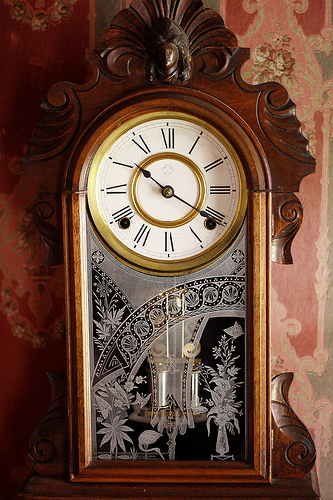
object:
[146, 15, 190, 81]
carved head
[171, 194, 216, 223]
hand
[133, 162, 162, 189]
hand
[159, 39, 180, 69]
carved face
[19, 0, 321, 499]
grandfather clock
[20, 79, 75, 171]
carving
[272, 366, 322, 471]
intricate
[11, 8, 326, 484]
wall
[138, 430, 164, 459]
stork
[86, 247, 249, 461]
glass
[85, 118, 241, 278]
face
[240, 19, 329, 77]
wallpaper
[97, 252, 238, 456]
design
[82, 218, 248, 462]
panel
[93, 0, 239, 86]
carving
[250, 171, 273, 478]
clock frame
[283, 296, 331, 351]
wallpaper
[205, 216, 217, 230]
keyhole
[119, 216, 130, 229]
keyhole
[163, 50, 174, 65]
light reflection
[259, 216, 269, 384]
light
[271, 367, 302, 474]
carving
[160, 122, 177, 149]
number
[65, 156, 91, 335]
frame